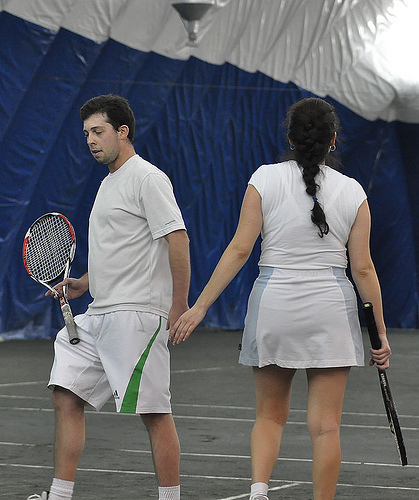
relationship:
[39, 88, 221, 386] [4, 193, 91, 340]
man holds racket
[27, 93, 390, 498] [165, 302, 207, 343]
couple touches hands